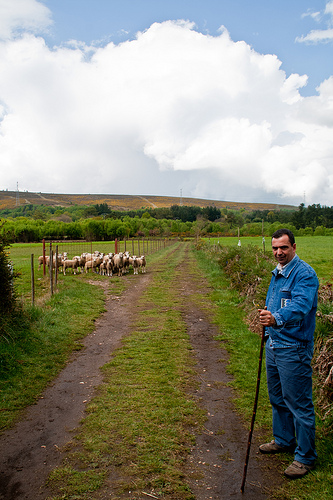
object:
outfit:
[265, 260, 320, 466]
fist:
[258, 308, 273, 327]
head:
[270, 226, 297, 267]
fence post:
[31, 252, 36, 307]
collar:
[270, 260, 295, 278]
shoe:
[257, 439, 278, 452]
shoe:
[284, 459, 309, 477]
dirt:
[0, 241, 282, 498]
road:
[133, 194, 156, 206]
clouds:
[0, 1, 332, 211]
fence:
[2, 234, 182, 305]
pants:
[264, 348, 319, 466]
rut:
[0, 270, 138, 498]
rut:
[179, 271, 273, 498]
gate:
[90, 238, 121, 253]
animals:
[136, 253, 147, 273]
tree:
[66, 220, 83, 239]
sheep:
[113, 251, 124, 276]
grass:
[0, 235, 333, 499]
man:
[258, 226, 320, 478]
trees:
[314, 225, 327, 236]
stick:
[240, 314, 266, 494]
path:
[0, 240, 275, 498]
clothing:
[263, 254, 319, 352]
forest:
[0, 201, 333, 244]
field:
[0, 231, 333, 498]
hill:
[0, 191, 302, 217]